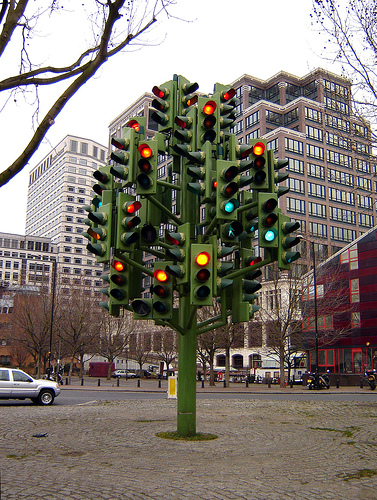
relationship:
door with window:
[351, 352, 366, 372] [318, 349, 323, 366]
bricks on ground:
[222, 455, 275, 499] [19, 402, 311, 482]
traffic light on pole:
[190, 243, 212, 305] [178, 300, 196, 433]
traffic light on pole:
[190, 243, 212, 305] [166, 309, 220, 446]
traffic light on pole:
[190, 243, 212, 305] [175, 282, 199, 438]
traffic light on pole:
[185, 236, 217, 311] [170, 332, 207, 438]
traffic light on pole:
[190, 243, 212, 305] [170, 332, 207, 438]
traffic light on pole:
[102, 249, 134, 309] [170, 332, 207, 438]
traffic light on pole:
[131, 136, 161, 197] [170, 332, 207, 438]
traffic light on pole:
[239, 135, 273, 192] [170, 332, 207, 438]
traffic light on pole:
[131, 136, 161, 197] [159, 178, 184, 195]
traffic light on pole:
[190, 243, 212, 305] [168, 324, 208, 437]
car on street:
[1, 365, 62, 412] [1, 362, 64, 404]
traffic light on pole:
[190, 243, 212, 305] [178, 143, 197, 435]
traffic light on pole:
[217, 158, 241, 219] [178, 143, 197, 435]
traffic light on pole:
[133, 137, 157, 191] [178, 143, 197, 435]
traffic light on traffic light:
[190, 243, 212, 305] [190, 243, 212, 305]